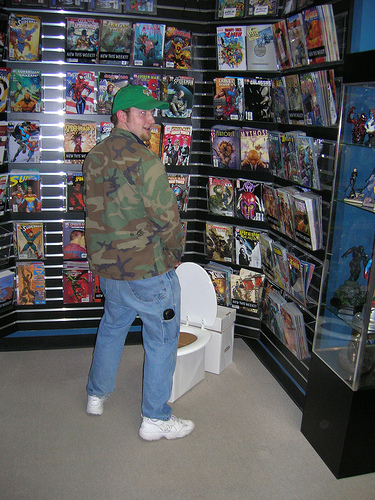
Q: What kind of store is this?
A: A comic book store.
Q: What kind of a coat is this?
A: A camo coat.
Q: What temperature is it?
A: 85 degrees.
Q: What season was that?
A: Summer.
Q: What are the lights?
A: Very bright.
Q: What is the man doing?
A: Urinating.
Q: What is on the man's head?
A: Baseball cap.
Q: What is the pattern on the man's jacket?
A: Camouflage.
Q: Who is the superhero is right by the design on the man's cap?
A: Spiderman.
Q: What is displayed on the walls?
A: Comic books.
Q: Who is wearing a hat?
A: The man.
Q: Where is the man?
A: In front of the toilet.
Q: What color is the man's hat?
A: Green.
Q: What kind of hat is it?
A: Baseball cap.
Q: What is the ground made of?
A: Carpet.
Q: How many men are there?
A: One.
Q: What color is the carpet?
A: Gray.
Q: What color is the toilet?
A: White.